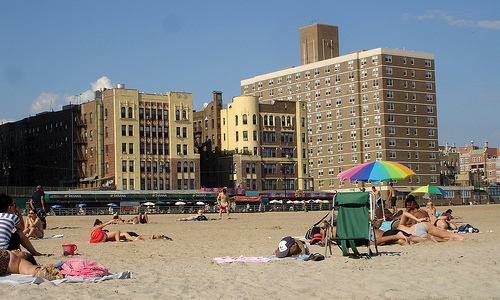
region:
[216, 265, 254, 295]
the sand is white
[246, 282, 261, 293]
the sand is white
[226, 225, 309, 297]
the sand is white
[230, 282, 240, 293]
the sand is white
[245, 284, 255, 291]
the sand is white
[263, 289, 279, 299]
the sand is white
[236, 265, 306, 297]
the sand is white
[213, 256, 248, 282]
the sand is white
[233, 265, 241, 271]
the sand is white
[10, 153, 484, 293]
A day at favorite beach.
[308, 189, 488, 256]
Family and friends enjoy together.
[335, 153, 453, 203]
Rainbow colored umbrellas sun protection.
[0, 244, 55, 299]
Woman spread out sunbather.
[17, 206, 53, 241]
Cell phone useage always evident.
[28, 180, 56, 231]
Man wearing jeans leaves beach.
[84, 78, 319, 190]
Older city buildings background.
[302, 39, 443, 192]
City apartment building hi-rise.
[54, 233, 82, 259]
Child's red sand pail left.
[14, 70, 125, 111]
Clouds or steam above building.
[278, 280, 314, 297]
the sand is white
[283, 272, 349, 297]
the sand is white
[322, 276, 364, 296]
the sand is white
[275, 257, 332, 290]
the sand is white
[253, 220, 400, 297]
the sand is white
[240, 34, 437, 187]
tall building is light brown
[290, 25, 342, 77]
chimney on tall building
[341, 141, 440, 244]
two rainbow umbrellas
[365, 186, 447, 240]
people sitting under rainbow umbrellas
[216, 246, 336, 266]
pink blanket on sand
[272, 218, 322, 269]
person lying on pink blanket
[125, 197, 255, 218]
white umbrellas in distance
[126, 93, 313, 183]
brown and tan building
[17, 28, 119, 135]
sky is blue with clouds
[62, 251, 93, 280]
small pink blanket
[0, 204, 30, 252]
girl's shirt is striped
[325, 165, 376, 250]
the chair is green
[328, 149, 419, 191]
umbrella is multi colored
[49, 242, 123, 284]
the towel is pink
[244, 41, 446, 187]
the building is brown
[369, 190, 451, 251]
people laying under umbrella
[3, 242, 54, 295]
person is laying down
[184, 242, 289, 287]
the towel is white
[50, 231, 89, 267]
the bucket is red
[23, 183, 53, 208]
man's shirt is black